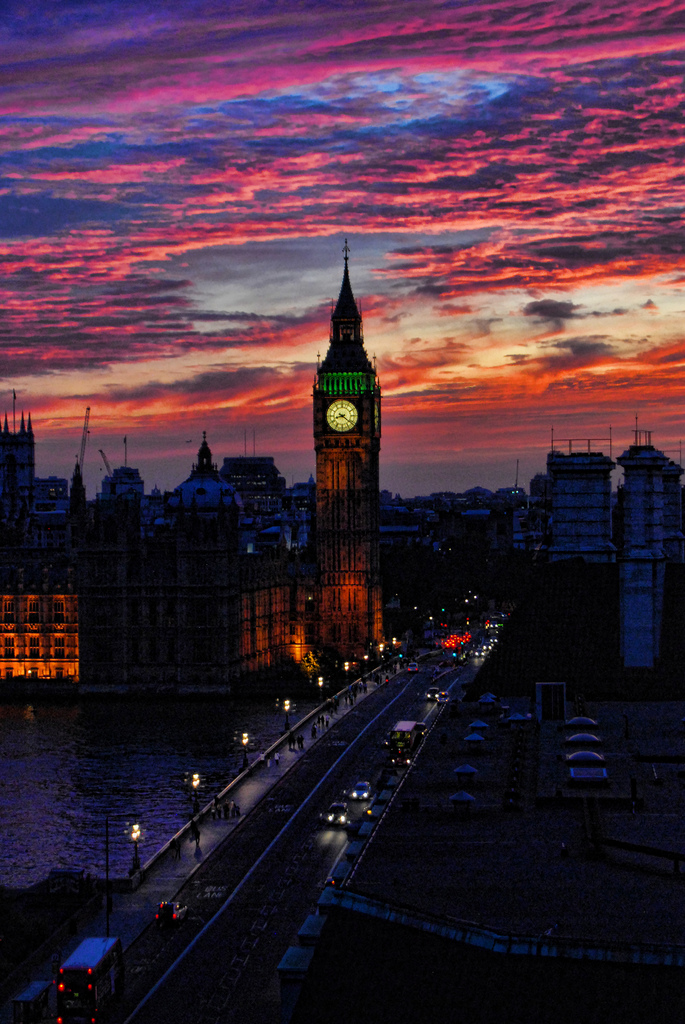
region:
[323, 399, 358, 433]
clock face on tall tower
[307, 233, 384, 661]
tall tower in the middle of a city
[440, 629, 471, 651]
group of cars with red tail lights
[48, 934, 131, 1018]
bus traveling on the road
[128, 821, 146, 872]
street light next to the water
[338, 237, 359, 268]
pinnacle on top of tall tower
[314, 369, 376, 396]
green lights above clock face on tower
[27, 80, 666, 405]
multi colored sunset in a night sky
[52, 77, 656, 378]
the sky is multi colored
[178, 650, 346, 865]
the lights line the street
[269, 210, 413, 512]
the clock tower is pointed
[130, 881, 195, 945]
the car lights are red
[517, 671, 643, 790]
the cars are parked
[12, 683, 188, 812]
the water is calm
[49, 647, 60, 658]
glass window on building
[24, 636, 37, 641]
glass window on building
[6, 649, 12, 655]
glass window on building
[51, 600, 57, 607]
glass window on building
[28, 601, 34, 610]
glass window on building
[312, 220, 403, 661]
clock tower with green lights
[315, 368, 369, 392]
green lights on the clock tower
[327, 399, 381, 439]
clocks on the clock tower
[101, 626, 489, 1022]
street next to the river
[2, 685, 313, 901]
river next to the street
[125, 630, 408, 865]
lights along the street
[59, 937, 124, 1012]
bus on the street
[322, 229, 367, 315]
spire on the clock tower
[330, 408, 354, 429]
hands on the clock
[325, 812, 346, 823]
two round illuminated car headlights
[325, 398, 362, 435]
one round illuminated clock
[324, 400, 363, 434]
one round white clock with black Roman numerals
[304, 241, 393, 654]
one stone building clock tower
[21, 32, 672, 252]
pink and blue and gold clouds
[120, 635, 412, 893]
row of illuminated street black metal lamps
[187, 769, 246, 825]
people walking next to lit street lamp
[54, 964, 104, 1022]
six red illuminated vehicle lights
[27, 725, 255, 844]
three illuminated street lamps next to body of water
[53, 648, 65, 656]
glass window on the building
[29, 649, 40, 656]
glass window on the building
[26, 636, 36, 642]
glass window on the building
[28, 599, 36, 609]
glass window on the building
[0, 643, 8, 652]
glass window on the building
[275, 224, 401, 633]
large lit clock tower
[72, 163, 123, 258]
white clouds in sky at sunset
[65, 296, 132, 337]
white clouds in sky at sunset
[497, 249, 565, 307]
white clouds in sky at sunset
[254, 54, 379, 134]
white clouds in sky at sunset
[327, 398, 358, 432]
clock on tower is round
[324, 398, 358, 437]
clock on tower is illuminated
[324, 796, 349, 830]
car travels down street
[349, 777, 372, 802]
car travels down street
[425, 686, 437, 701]
car travels down street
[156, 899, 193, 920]
car travels down street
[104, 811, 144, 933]
street light is illuminated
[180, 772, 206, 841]
street light is illuminated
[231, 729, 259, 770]
street light is illuminated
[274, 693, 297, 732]
street light is illuminated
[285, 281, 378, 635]
brown clock tower at night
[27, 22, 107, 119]
pink clouds in blue sky at sunset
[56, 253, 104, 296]
pink clouds in blue sky at sunset